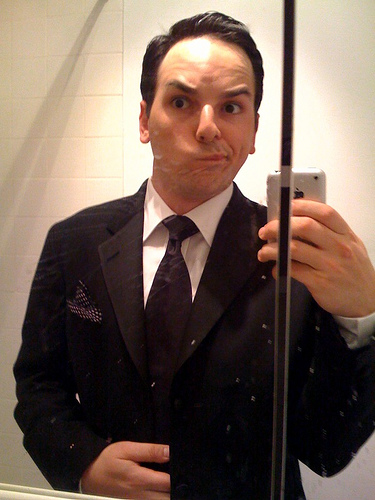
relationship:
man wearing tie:
[96, 41, 295, 335] [158, 216, 204, 320]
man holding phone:
[96, 41, 295, 335] [269, 156, 324, 209]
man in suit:
[96, 41, 295, 335] [82, 221, 294, 438]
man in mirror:
[96, 41, 295, 335] [238, 267, 277, 377]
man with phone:
[96, 41, 295, 335] [269, 156, 324, 209]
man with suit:
[96, 41, 295, 335] [82, 221, 294, 438]